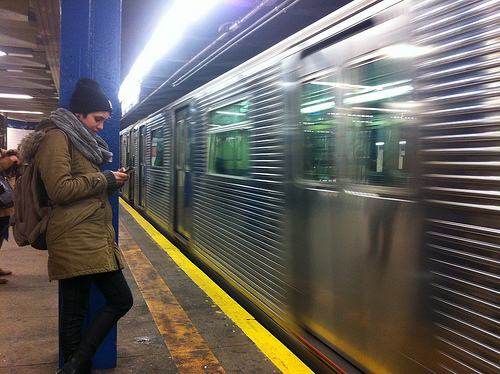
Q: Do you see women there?
A: Yes, there is a woman.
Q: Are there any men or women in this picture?
A: Yes, there is a woman.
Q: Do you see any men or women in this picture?
A: Yes, there is a woman.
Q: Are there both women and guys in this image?
A: No, there is a woman but no guys.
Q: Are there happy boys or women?
A: Yes, there is a happy woman.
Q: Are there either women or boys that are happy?
A: Yes, the woman is happy.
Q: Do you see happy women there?
A: Yes, there is a happy woman.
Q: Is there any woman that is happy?
A: Yes, there is a woman that is happy.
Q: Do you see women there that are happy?
A: Yes, there is a woman that is happy.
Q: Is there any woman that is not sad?
A: Yes, there is a happy woman.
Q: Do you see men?
A: No, there are no men.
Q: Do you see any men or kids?
A: No, there are no men or kids.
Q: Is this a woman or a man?
A: This is a woman.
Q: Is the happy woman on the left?
A: Yes, the woman is on the left of the image.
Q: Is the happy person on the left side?
A: Yes, the woman is on the left of the image.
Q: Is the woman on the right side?
A: No, the woman is on the left of the image.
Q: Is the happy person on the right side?
A: No, the woman is on the left of the image.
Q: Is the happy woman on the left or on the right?
A: The woman is on the left of the image.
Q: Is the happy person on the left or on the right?
A: The woman is on the left of the image.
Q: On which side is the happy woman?
A: The woman is on the left of the image.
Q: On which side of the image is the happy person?
A: The woman is on the left of the image.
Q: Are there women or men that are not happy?
A: No, there is a woman but she is happy.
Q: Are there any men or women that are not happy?
A: No, there is a woman but she is happy.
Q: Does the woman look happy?
A: Yes, the woman is happy.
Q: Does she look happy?
A: Yes, the woman is happy.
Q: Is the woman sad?
A: No, the woman is happy.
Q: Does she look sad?
A: No, the woman is happy.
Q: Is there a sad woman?
A: No, there is a woman but she is happy.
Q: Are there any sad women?
A: No, there is a woman but she is happy.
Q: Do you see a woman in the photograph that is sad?
A: No, there is a woman but she is happy.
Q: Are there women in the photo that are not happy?
A: No, there is a woman but she is happy.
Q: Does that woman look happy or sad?
A: The woman is happy.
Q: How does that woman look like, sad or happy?
A: The woman is happy.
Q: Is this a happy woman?
A: Yes, this is a happy woman.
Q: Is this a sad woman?
A: No, this is a happy woman.